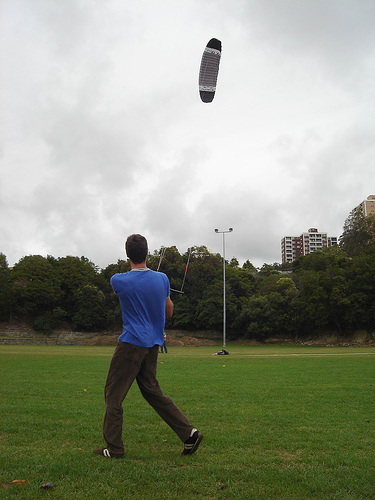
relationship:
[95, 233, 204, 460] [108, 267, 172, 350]
man ia wearing shirt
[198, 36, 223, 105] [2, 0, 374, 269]
kite in sky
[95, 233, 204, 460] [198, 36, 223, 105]
man flying kite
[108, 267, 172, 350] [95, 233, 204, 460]
shirt on man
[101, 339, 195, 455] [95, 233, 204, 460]
pants are on man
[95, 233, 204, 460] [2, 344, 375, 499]
man standing in field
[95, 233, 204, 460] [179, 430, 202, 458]
man wearing shoe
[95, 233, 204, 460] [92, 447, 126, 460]
man wearing shoe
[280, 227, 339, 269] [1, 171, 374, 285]
building in background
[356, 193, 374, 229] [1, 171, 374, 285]
building in background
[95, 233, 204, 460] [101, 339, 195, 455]
man wearing pants